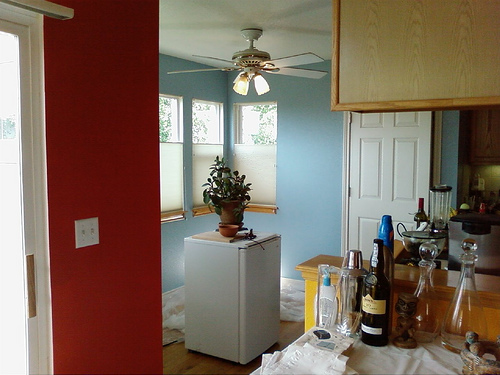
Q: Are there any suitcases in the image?
A: No, there are no suitcases.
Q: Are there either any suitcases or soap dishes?
A: No, there are no suitcases or soap dishes.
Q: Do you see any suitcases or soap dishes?
A: No, there are no suitcases or soap dishes.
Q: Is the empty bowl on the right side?
A: Yes, the bowl is on the right of the image.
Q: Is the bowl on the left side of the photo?
A: No, the bowl is on the right of the image.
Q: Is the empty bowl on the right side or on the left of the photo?
A: The bowl is on the right of the image.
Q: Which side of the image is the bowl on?
A: The bowl is on the right of the image.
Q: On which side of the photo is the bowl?
A: The bowl is on the right of the image.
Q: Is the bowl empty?
A: Yes, the bowl is empty.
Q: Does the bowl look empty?
A: Yes, the bowl is empty.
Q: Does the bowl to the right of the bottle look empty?
A: Yes, the bowl is empty.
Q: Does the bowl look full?
A: No, the bowl is empty.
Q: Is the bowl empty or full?
A: The bowl is empty.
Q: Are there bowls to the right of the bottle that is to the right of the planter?
A: Yes, there is a bowl to the right of the bottle.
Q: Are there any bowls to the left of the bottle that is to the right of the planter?
A: No, the bowl is to the right of the bottle.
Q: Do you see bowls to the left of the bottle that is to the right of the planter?
A: No, the bowl is to the right of the bottle.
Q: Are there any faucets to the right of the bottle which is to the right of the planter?
A: No, there is a bowl to the right of the bottle.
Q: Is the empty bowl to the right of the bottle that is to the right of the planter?
A: Yes, the bowl is to the right of the bottle.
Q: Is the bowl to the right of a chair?
A: No, the bowl is to the right of the bottle.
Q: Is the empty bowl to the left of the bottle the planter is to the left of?
A: No, the bowl is to the right of the bottle.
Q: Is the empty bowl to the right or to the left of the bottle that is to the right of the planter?
A: The bowl is to the right of the bottle.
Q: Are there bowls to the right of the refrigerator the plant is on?
A: Yes, there is a bowl to the right of the freezer.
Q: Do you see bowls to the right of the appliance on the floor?
A: Yes, there is a bowl to the right of the freezer.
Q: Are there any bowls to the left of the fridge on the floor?
A: No, the bowl is to the right of the refrigerator.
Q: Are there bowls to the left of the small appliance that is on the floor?
A: No, the bowl is to the right of the refrigerator.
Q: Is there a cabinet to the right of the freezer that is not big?
A: No, there is a bowl to the right of the freezer.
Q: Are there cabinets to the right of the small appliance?
A: No, there is a bowl to the right of the freezer.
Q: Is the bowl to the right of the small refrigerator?
A: Yes, the bowl is to the right of the freezer.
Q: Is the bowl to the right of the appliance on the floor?
A: Yes, the bowl is to the right of the freezer.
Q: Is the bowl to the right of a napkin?
A: No, the bowl is to the right of the freezer.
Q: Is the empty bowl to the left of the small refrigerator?
A: No, the bowl is to the right of the freezer.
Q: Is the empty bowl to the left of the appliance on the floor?
A: No, the bowl is to the right of the freezer.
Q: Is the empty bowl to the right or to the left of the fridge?
A: The bowl is to the right of the fridge.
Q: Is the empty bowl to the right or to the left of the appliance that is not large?
A: The bowl is to the right of the fridge.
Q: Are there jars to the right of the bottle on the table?
A: No, there is a bowl to the right of the bottle.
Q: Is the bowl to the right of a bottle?
A: Yes, the bowl is to the right of a bottle.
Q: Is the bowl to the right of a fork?
A: No, the bowl is to the right of a bottle.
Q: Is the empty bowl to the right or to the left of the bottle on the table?
A: The bowl is to the right of the bottle.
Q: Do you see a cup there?
A: No, there are no cups.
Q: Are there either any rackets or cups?
A: No, there are no cups or rackets.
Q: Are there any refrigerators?
A: Yes, there is a refrigerator.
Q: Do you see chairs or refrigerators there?
A: Yes, there is a refrigerator.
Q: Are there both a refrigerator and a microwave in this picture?
A: No, there is a refrigerator but no microwaves.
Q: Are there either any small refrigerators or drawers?
A: Yes, there is a small refrigerator.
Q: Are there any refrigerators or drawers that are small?
A: Yes, the refrigerator is small.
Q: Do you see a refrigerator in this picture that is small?
A: Yes, there is a small refrigerator.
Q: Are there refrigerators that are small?
A: Yes, there is a refrigerator that is small.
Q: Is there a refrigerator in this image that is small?
A: Yes, there is a refrigerator that is small.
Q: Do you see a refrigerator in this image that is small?
A: Yes, there is a refrigerator that is small.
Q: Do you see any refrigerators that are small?
A: Yes, there is a refrigerator that is small.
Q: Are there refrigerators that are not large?
A: Yes, there is a small refrigerator.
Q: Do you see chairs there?
A: No, there are no chairs.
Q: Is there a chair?
A: No, there are no chairs.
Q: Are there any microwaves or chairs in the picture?
A: No, there are no chairs or microwaves.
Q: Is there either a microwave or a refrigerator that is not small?
A: No, there is a refrigerator but it is small.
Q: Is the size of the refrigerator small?
A: Yes, the refrigerator is small.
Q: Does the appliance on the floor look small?
A: Yes, the refrigerator is small.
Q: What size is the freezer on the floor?
A: The freezer is small.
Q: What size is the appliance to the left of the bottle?
A: The freezer is small.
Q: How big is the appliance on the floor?
A: The refrigerator is small.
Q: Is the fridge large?
A: No, the fridge is small.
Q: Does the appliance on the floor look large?
A: No, the freezer is small.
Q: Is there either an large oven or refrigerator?
A: No, there is a refrigerator but it is small.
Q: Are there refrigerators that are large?
A: No, there is a refrigerator but it is small.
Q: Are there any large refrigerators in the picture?
A: No, there is a refrigerator but it is small.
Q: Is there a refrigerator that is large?
A: No, there is a refrigerator but it is small.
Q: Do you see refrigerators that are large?
A: No, there is a refrigerator but it is small.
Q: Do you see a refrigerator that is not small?
A: No, there is a refrigerator but it is small.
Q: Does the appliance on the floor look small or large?
A: The fridge is small.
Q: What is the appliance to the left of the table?
A: The appliance is a refrigerator.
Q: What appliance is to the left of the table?
A: The appliance is a refrigerator.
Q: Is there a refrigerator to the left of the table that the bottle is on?
A: Yes, there is a refrigerator to the left of the table.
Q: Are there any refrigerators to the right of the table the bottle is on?
A: No, the refrigerator is to the left of the table.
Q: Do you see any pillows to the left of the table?
A: No, there is a refrigerator to the left of the table.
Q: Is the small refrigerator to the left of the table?
A: Yes, the refrigerator is to the left of the table.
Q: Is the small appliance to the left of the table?
A: Yes, the refrigerator is to the left of the table.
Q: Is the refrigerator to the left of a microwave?
A: No, the refrigerator is to the left of the table.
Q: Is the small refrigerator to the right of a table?
A: No, the refrigerator is to the left of a table.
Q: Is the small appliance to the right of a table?
A: No, the refrigerator is to the left of a table.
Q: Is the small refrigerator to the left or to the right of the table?
A: The refrigerator is to the left of the table.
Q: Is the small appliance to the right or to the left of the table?
A: The refrigerator is to the left of the table.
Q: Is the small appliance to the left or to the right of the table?
A: The refrigerator is to the left of the table.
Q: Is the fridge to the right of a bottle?
A: No, the fridge is to the left of a bottle.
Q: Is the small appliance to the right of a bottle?
A: No, the fridge is to the left of a bottle.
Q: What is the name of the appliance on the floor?
A: The appliance is a refrigerator.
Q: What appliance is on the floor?
A: The appliance is a refrigerator.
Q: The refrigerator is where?
A: The refrigerator is on the floor.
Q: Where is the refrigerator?
A: The refrigerator is on the floor.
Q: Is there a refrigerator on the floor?
A: Yes, there is a refrigerator on the floor.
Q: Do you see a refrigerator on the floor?
A: Yes, there is a refrigerator on the floor.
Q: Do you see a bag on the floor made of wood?
A: No, there is a refrigerator on the floor.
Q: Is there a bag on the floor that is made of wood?
A: No, there is a refrigerator on the floor.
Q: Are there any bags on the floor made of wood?
A: No, there is a refrigerator on the floor.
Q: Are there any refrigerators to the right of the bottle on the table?
A: No, the refrigerator is to the left of the bottle.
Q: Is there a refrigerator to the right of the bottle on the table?
A: No, the refrigerator is to the left of the bottle.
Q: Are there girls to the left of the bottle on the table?
A: No, there is a refrigerator to the left of the bottle.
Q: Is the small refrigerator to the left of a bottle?
A: Yes, the fridge is to the left of a bottle.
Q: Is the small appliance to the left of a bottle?
A: Yes, the fridge is to the left of a bottle.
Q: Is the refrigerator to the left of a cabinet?
A: No, the refrigerator is to the left of a bottle.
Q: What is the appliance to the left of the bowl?
A: The appliance is a refrigerator.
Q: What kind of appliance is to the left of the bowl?
A: The appliance is a refrigerator.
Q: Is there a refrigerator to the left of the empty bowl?
A: Yes, there is a refrigerator to the left of the bowl.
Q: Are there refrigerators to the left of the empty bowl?
A: Yes, there is a refrigerator to the left of the bowl.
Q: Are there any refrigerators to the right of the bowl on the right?
A: No, the refrigerator is to the left of the bowl.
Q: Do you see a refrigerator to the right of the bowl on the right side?
A: No, the refrigerator is to the left of the bowl.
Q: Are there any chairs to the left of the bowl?
A: No, there is a refrigerator to the left of the bowl.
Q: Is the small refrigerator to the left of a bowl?
A: Yes, the refrigerator is to the left of a bowl.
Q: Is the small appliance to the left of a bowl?
A: Yes, the refrigerator is to the left of a bowl.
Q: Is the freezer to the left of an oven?
A: No, the freezer is to the left of a bowl.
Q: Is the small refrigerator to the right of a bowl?
A: No, the freezer is to the left of a bowl.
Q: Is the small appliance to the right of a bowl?
A: No, the freezer is to the left of a bowl.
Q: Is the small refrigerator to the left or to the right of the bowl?
A: The freezer is to the left of the bowl.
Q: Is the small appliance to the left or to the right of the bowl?
A: The freezer is to the left of the bowl.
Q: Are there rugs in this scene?
A: No, there are no rugs.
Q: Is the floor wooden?
A: Yes, the floor is wooden.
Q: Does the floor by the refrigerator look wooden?
A: Yes, the floor is wooden.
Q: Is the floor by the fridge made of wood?
A: Yes, the floor is made of wood.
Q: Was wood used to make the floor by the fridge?
A: Yes, the floor is made of wood.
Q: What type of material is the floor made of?
A: The floor is made of wood.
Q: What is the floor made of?
A: The floor is made of wood.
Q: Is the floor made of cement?
A: No, the floor is made of wood.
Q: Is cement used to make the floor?
A: No, the floor is made of wood.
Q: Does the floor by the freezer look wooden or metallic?
A: The floor is wooden.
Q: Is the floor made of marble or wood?
A: The floor is made of wood.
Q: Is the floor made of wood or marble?
A: The floor is made of wood.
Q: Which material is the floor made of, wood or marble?
A: The floor is made of wood.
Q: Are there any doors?
A: Yes, there is a door.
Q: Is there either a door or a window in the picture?
A: Yes, there is a door.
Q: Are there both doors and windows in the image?
A: Yes, there are both a door and a window.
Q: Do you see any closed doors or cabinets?
A: Yes, there is a closed door.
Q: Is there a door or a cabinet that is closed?
A: Yes, the door is closed.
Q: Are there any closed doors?
A: Yes, there is a closed door.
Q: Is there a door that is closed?
A: Yes, there is a door that is closed.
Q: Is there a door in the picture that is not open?
A: Yes, there is an closed door.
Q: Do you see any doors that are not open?
A: Yes, there is an closed door.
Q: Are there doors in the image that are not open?
A: Yes, there is an closed door.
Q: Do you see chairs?
A: No, there are no chairs.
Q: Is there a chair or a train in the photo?
A: No, there are no chairs or trains.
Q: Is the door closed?
A: Yes, the door is closed.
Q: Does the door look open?
A: No, the door is closed.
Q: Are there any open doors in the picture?
A: No, there is a door but it is closed.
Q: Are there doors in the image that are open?
A: No, there is a door but it is closed.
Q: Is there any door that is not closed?
A: No, there is a door but it is closed.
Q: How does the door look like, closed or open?
A: The door is closed.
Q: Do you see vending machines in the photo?
A: No, there are no vending machines.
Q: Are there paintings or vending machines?
A: No, there are no vending machines or paintings.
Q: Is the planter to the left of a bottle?
A: Yes, the planter is to the left of a bottle.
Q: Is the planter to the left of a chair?
A: No, the planter is to the left of a bottle.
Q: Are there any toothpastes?
A: No, there are no toothpastes.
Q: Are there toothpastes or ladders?
A: No, there are no toothpastes or ladders.